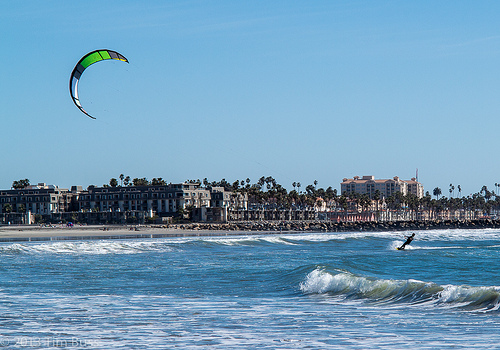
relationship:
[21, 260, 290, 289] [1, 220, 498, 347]
blue water in ocean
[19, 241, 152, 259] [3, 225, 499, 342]
foam in water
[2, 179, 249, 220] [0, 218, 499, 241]
buildings on beach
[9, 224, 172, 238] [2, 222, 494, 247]
sand on beach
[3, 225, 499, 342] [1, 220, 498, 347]
water in ocean